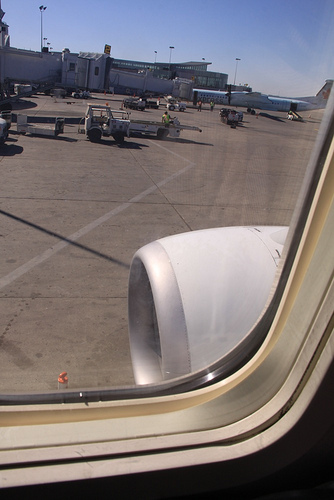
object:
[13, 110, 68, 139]
cart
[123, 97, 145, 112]
cart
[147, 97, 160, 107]
cart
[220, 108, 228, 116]
luggage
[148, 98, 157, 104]
luggage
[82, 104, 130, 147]
jeep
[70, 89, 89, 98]
vehicle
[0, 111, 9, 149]
vehicle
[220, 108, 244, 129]
vehicle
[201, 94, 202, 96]
windows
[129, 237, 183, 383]
frame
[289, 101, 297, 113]
door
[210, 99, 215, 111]
workers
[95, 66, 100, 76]
windows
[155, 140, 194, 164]
white line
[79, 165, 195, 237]
white line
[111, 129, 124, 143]
wheels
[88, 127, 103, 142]
wheels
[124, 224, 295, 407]
engine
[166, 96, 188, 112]
carts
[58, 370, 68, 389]
cone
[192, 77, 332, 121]
airplane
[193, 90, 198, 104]
doors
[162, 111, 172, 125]
person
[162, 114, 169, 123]
vest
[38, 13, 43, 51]
pole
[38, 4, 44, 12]
lights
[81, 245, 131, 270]
shadow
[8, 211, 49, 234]
black line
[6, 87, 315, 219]
road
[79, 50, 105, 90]
building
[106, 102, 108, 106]
light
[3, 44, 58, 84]
building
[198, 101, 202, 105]
vest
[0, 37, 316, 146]
airport